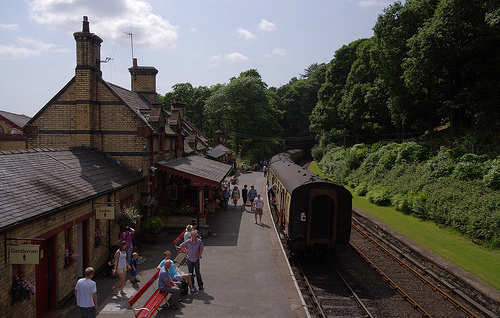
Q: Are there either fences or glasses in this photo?
A: No, there are no fences or glasses.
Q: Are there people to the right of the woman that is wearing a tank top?
A: Yes, there is a person to the right of the woman.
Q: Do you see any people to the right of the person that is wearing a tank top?
A: Yes, there is a person to the right of the woman.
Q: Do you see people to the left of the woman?
A: No, the person is to the right of the woman.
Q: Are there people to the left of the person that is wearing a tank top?
A: No, the person is to the right of the woman.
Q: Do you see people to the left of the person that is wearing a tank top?
A: No, the person is to the right of the woman.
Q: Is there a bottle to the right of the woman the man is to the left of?
A: No, there is a person to the right of the woman.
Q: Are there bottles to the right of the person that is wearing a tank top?
A: No, there is a person to the right of the woman.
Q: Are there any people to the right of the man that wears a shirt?
A: Yes, there is a person to the right of the man.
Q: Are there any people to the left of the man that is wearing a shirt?
A: No, the person is to the right of the man.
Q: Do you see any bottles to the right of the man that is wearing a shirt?
A: No, there is a person to the right of the man.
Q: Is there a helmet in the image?
A: No, there are no helmets.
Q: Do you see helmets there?
A: No, there are no helmets.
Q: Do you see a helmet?
A: No, there are no helmets.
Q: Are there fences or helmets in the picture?
A: No, there are no helmets or fences.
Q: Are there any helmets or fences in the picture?
A: No, there are no helmets or fences.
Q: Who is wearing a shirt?
A: The man is wearing a shirt.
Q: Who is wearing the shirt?
A: The man is wearing a shirt.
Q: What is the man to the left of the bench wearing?
A: The man is wearing a shirt.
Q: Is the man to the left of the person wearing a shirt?
A: Yes, the man is wearing a shirt.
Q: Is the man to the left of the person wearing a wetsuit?
A: No, the man is wearing a shirt.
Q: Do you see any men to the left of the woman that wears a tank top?
A: Yes, there is a man to the left of the woman.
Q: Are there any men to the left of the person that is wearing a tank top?
A: Yes, there is a man to the left of the woman.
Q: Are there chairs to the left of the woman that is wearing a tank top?
A: No, there is a man to the left of the woman.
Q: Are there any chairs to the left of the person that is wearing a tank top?
A: No, there is a man to the left of the woman.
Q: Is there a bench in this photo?
A: Yes, there is a bench.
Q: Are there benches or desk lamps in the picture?
A: Yes, there is a bench.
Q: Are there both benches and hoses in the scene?
A: No, there is a bench but no hoses.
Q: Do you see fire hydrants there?
A: No, there are no fire hydrants.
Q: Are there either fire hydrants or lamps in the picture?
A: No, there are no fire hydrants or lamps.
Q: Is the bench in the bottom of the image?
A: Yes, the bench is in the bottom of the image.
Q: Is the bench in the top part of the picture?
A: No, the bench is in the bottom of the image.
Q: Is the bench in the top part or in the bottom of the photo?
A: The bench is in the bottom of the image.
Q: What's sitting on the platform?
A: The bench is sitting on the platform.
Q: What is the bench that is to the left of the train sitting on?
A: The bench is sitting on the platform.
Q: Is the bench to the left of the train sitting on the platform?
A: Yes, the bench is sitting on the platform.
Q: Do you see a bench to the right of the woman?
A: Yes, there is a bench to the right of the woman.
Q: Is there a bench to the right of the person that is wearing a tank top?
A: Yes, there is a bench to the right of the woman.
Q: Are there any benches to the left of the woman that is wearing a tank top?
A: No, the bench is to the right of the woman.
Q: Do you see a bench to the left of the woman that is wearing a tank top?
A: No, the bench is to the right of the woman.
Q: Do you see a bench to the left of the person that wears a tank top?
A: No, the bench is to the right of the woman.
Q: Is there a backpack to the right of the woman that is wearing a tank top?
A: No, there is a bench to the right of the woman.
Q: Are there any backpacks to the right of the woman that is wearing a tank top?
A: No, there is a bench to the right of the woman.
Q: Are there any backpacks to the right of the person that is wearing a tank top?
A: No, there is a bench to the right of the woman.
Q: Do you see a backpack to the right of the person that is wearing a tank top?
A: No, there is a bench to the right of the woman.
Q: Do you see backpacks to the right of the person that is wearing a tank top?
A: No, there is a bench to the right of the woman.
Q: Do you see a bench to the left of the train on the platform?
A: Yes, there is a bench to the left of the train.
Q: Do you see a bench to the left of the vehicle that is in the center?
A: Yes, there is a bench to the left of the train.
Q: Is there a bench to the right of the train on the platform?
A: No, the bench is to the left of the train.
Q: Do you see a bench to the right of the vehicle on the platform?
A: No, the bench is to the left of the train.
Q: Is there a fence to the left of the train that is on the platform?
A: No, there is a bench to the left of the train.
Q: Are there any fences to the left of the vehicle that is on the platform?
A: No, there is a bench to the left of the train.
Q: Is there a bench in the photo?
A: Yes, there is a bench.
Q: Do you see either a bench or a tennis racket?
A: Yes, there is a bench.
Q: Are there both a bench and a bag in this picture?
A: No, there is a bench but no bags.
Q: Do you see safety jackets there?
A: No, there are no safety jackets.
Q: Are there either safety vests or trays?
A: No, there are no safety vests or trays.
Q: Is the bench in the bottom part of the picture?
A: Yes, the bench is in the bottom of the image.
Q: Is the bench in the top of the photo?
A: No, the bench is in the bottom of the image.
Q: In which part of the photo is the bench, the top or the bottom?
A: The bench is in the bottom of the image.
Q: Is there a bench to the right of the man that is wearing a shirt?
A: Yes, there is a bench to the right of the man.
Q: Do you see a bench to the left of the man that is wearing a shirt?
A: No, the bench is to the right of the man.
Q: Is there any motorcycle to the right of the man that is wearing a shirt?
A: No, there is a bench to the right of the man.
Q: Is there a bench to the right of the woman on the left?
A: Yes, there is a bench to the right of the woman.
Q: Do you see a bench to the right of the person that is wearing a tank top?
A: Yes, there is a bench to the right of the woman.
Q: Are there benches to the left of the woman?
A: No, the bench is to the right of the woman.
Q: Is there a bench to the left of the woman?
A: No, the bench is to the right of the woman.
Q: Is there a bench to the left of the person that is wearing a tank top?
A: No, the bench is to the right of the woman.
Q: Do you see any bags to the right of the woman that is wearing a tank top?
A: No, there is a bench to the right of the woman.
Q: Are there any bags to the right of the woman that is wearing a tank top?
A: No, there is a bench to the right of the woman.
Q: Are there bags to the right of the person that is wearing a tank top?
A: No, there is a bench to the right of the woman.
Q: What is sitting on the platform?
A: The bench is sitting on the platform.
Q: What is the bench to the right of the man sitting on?
A: The bench is sitting on the platform.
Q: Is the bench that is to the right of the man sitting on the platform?
A: Yes, the bench is sitting on the platform.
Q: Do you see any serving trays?
A: No, there are no serving trays.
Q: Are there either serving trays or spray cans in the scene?
A: No, there are no serving trays or spray cans.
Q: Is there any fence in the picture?
A: No, there are no fences.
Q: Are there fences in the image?
A: No, there are no fences.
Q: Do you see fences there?
A: No, there are no fences.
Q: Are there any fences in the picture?
A: No, there are no fences.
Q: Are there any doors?
A: Yes, there is a door.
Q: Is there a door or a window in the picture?
A: Yes, there is a door.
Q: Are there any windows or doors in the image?
A: Yes, there is a door.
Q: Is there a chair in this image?
A: No, there are no chairs.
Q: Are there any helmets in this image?
A: No, there are no helmets.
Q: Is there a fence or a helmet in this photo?
A: No, there are no helmets or fences.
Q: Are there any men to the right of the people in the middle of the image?
A: Yes, there is a man to the right of the people.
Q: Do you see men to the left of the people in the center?
A: No, the man is to the right of the people.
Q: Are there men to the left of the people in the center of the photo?
A: No, the man is to the right of the people.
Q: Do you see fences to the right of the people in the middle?
A: No, there is a man to the right of the people.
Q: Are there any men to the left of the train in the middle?
A: Yes, there is a man to the left of the train.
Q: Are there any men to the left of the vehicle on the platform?
A: Yes, there is a man to the left of the train.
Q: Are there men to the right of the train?
A: No, the man is to the left of the train.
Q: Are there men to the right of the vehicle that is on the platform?
A: No, the man is to the left of the train.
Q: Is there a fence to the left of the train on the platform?
A: No, there is a man to the left of the train.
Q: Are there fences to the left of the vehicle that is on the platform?
A: No, there is a man to the left of the train.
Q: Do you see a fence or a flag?
A: No, there are no fences or flags.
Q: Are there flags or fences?
A: No, there are no fences or flags.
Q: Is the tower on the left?
A: Yes, the tower is on the left of the image.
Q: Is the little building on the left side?
A: Yes, the tower is on the left of the image.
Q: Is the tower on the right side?
A: No, the tower is on the left of the image.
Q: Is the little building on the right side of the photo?
A: No, the tower is on the left of the image.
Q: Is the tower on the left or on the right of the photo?
A: The tower is on the left of the image.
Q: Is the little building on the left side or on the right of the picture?
A: The tower is on the left of the image.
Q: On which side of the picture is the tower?
A: The tower is on the left of the image.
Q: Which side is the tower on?
A: The tower is on the left of the image.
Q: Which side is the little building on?
A: The tower is on the left of the image.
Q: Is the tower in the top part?
A: Yes, the tower is in the top of the image.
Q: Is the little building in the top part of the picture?
A: Yes, the tower is in the top of the image.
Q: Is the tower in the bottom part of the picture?
A: No, the tower is in the top of the image.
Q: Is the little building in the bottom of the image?
A: No, the tower is in the top of the image.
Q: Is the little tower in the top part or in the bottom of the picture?
A: The tower is in the top of the image.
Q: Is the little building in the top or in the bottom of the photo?
A: The tower is in the top of the image.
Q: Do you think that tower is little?
A: Yes, the tower is little.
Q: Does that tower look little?
A: Yes, the tower is little.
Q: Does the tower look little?
A: Yes, the tower is little.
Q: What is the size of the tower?
A: The tower is little.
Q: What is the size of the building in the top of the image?
A: The tower is little.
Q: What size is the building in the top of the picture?
A: The tower is little.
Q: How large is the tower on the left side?
A: The tower is little.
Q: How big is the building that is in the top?
A: The tower is little.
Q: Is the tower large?
A: No, the tower is little.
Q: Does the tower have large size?
A: No, the tower is little.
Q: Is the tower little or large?
A: The tower is little.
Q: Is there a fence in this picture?
A: No, there are no fences.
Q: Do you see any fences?
A: No, there are no fences.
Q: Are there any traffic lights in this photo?
A: No, there are no traffic lights.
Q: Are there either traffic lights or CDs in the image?
A: No, there are no traffic lights or cds.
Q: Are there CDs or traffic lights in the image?
A: No, there are no traffic lights or cds.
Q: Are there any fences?
A: No, there are no fences.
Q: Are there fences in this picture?
A: No, there are no fences.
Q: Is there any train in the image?
A: Yes, there is a train.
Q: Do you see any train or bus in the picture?
A: Yes, there is a train.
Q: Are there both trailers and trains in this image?
A: No, there is a train but no trailers.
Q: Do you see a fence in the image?
A: No, there are no fences.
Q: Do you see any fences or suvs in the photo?
A: No, there are no fences or suvs.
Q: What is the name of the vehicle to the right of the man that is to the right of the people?
A: The vehicle is a train.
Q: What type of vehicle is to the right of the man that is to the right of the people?
A: The vehicle is a train.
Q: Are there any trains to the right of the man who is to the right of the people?
A: Yes, there is a train to the right of the man.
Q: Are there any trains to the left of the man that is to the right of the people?
A: No, the train is to the right of the man.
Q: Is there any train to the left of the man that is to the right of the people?
A: No, the train is to the right of the man.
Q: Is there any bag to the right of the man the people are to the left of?
A: No, there is a train to the right of the man.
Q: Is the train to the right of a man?
A: Yes, the train is to the right of a man.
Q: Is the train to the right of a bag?
A: No, the train is to the right of a man.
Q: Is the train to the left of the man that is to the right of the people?
A: No, the train is to the right of the man.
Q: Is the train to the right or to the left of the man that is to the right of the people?
A: The train is to the right of the man.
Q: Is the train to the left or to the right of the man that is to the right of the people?
A: The train is to the right of the man.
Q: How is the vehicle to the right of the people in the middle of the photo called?
A: The vehicle is a train.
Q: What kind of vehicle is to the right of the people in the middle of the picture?
A: The vehicle is a train.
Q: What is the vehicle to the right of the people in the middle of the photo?
A: The vehicle is a train.